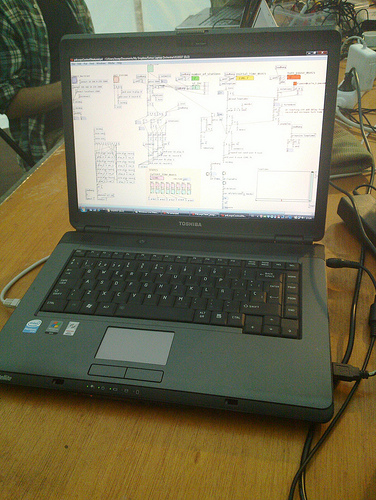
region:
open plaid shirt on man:
[0, 3, 49, 100]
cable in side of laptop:
[328, 354, 362, 385]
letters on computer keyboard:
[93, 263, 203, 298]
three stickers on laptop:
[21, 314, 79, 338]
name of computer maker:
[171, 217, 211, 230]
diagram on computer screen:
[110, 70, 310, 186]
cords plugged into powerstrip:
[333, 72, 368, 126]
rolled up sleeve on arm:
[0, 67, 26, 108]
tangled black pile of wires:
[311, 4, 365, 22]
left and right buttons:
[81, 362, 173, 383]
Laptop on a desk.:
[35, 28, 374, 450]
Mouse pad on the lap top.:
[69, 314, 195, 382]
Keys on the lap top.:
[44, 238, 299, 349]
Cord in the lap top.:
[317, 333, 373, 392]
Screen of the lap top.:
[74, 63, 342, 264]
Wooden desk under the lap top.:
[15, 382, 237, 498]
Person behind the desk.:
[3, 2, 230, 197]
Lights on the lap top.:
[71, 374, 169, 414]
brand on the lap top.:
[165, 213, 256, 239]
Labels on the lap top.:
[19, 308, 97, 360]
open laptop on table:
[12, 20, 359, 391]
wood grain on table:
[152, 431, 230, 476]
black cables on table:
[284, 432, 337, 491]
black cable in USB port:
[326, 356, 358, 384]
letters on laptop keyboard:
[86, 273, 231, 302]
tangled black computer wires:
[328, 4, 367, 30]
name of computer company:
[170, 218, 211, 228]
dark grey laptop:
[22, 27, 321, 410]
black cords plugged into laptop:
[318, 243, 372, 432]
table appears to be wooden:
[12, 403, 247, 487]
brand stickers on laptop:
[16, 313, 78, 335]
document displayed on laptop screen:
[64, 47, 313, 218]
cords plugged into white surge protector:
[335, 29, 371, 127]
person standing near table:
[0, 0, 95, 205]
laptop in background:
[161, 0, 257, 33]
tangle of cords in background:
[294, 0, 369, 42]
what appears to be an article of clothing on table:
[326, 98, 374, 194]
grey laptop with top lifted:
[7, 44, 342, 410]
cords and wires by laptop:
[325, 47, 370, 468]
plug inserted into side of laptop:
[320, 353, 362, 389]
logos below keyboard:
[16, 289, 84, 335]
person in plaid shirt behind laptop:
[4, 2, 95, 164]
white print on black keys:
[65, 247, 292, 323]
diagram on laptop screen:
[67, 47, 325, 220]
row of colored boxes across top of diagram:
[63, 70, 310, 81]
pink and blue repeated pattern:
[138, 176, 198, 194]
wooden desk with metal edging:
[6, 137, 57, 247]